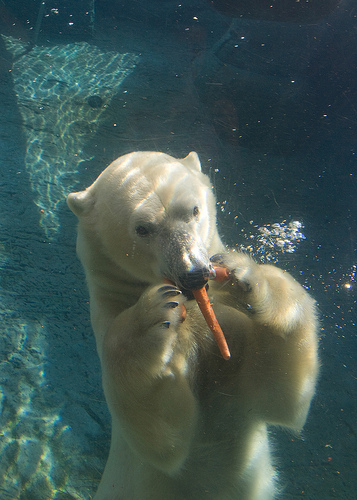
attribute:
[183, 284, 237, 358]
carrot — eating by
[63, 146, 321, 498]
bear — eating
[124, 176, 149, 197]
fur — white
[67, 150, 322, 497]
polar bear — eating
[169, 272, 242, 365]
carrot — long, orange